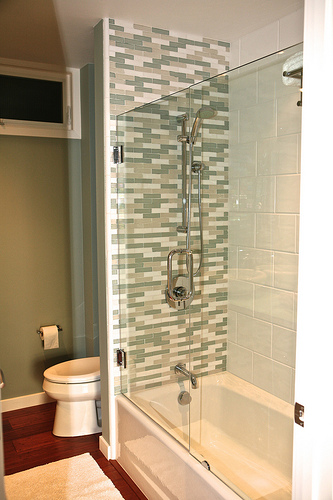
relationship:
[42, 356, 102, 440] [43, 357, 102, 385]
toilet has seat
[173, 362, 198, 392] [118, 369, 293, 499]
faucet in bathtub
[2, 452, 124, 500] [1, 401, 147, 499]
rug on floor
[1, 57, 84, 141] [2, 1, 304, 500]
window in bathroom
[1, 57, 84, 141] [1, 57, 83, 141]
window has frame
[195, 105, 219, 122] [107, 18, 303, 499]
shower head in shower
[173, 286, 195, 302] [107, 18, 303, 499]
hot and cold knob in shower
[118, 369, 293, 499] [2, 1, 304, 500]
bathtub in bathroom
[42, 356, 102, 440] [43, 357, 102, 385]
toilet has lid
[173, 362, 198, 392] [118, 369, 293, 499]
faucet near bathtub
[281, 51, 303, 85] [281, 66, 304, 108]
towel on rack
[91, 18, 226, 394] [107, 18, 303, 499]
wall inside shower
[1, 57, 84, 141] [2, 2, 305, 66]
window near ceiling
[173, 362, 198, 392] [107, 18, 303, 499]
faucet in shower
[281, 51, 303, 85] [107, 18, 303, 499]
towel in shower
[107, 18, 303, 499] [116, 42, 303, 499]
shower has shower door